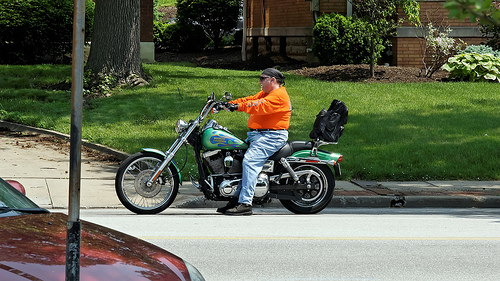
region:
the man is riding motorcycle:
[124, 56, 354, 271]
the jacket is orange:
[214, 77, 316, 135]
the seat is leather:
[271, 142, 292, 155]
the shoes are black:
[213, 197, 259, 218]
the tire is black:
[116, 152, 228, 229]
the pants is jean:
[227, 124, 312, 226]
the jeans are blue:
[209, 127, 334, 219]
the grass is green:
[359, 85, 469, 150]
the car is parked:
[2, 220, 79, 273]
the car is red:
[17, 215, 69, 278]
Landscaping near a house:
[288, 8, 498, 85]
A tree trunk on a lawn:
[86, 11, 167, 123]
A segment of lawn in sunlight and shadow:
[366, 85, 472, 158]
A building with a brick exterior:
[238, 6, 492, 65]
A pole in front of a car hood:
[14, 80, 116, 274]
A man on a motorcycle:
[105, 58, 376, 221]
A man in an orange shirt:
[223, 54, 298, 137]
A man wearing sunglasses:
[241, 56, 297, 98]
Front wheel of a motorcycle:
[111, 144, 182, 218]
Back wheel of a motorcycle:
[278, 148, 335, 217]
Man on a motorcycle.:
[100, 81, 406, 232]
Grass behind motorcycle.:
[176, 72, 469, 174]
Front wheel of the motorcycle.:
[110, 129, 223, 254]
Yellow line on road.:
[212, 235, 495, 257]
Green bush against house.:
[310, 8, 412, 83]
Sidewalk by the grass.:
[375, 150, 492, 230]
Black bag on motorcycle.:
[305, 92, 390, 165]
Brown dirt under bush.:
[301, 41, 473, 117]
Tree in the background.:
[89, 12, 188, 99]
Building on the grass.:
[235, 3, 467, 91]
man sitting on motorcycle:
[116, 48, 359, 210]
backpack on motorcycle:
[308, 89, 359, 156]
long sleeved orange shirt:
[225, 77, 294, 145]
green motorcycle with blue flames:
[141, 88, 348, 217]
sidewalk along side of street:
[255, 168, 497, 219]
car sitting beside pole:
[3, 4, 200, 279]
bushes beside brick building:
[302, 6, 499, 97]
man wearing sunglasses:
[253, 62, 274, 97]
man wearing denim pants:
[231, 124, 280, 221]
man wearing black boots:
[206, 190, 261, 224]